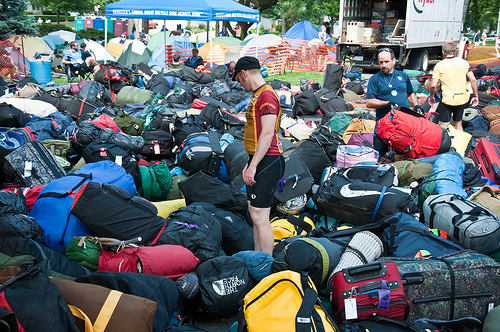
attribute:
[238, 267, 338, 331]
bag — yellow, large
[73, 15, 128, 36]
potties — rowed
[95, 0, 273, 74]
tent — blue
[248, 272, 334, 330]
bag — duffel, yellow, bright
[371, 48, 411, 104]
man — wearing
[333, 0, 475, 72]
truck — large, box, white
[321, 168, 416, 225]
bag — full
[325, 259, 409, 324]
case — red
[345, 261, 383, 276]
handle — black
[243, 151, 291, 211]
shorts — black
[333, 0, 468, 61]
truck — white, box, large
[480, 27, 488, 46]
person — walking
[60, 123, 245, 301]
bags — lot, these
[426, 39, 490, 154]
person — wearing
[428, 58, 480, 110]
yellow shirt — worn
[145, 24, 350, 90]
fence — orange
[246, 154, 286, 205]
shorts — these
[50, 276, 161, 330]
bag — brown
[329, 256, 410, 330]
suitcase — red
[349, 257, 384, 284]
handle — black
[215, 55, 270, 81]
hat — black